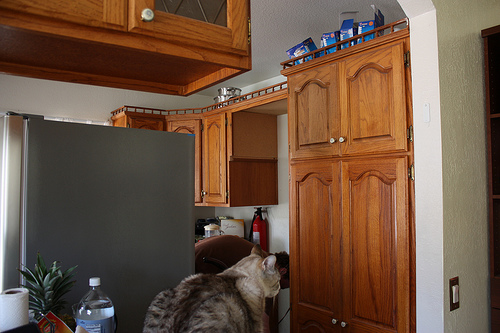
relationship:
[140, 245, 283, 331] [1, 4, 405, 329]
cat sitting in kitchen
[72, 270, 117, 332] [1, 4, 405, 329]
bottle in kitchen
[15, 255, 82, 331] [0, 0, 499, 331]
pineapple in kitchen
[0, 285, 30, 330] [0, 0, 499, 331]
paper towels in kitchen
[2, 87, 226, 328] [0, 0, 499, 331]
refrigerator in kitchen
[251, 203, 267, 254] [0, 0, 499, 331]
extinguisher in kitchen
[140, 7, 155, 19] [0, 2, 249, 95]
knob for cupboard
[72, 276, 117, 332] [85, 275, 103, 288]
bottle of water with top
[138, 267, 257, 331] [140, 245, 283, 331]
body of cat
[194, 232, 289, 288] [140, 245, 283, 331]
person behind cat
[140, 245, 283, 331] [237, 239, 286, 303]
cat has head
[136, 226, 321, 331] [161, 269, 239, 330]
cat has back fur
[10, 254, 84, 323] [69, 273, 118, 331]
fronds beside water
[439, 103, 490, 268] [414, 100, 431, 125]
white wall near light switch